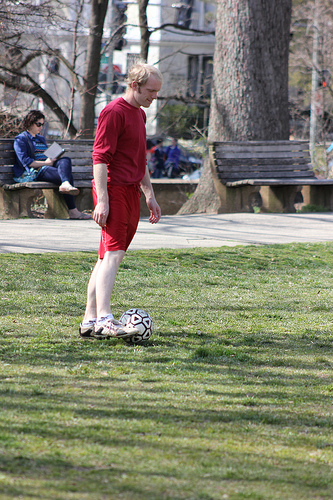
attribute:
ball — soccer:
[111, 310, 153, 341]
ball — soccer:
[119, 306, 147, 339]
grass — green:
[129, 392, 210, 425]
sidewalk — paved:
[184, 219, 243, 235]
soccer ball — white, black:
[118, 306, 153, 344]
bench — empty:
[207, 139, 331, 215]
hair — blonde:
[128, 62, 162, 94]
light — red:
[320, 79, 328, 89]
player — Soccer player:
[78, 61, 162, 338]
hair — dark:
[21, 109, 45, 128]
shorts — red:
[90, 175, 142, 256]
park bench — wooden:
[211, 135, 319, 211]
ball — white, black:
[113, 305, 159, 341]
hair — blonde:
[121, 61, 162, 90]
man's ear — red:
[128, 75, 143, 92]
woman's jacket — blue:
[12, 129, 53, 174]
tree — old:
[168, 0, 307, 217]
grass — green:
[0, 241, 332, 496]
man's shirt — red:
[89, 98, 157, 192]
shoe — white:
[88, 313, 132, 339]